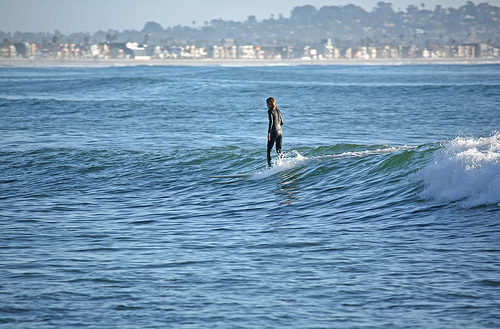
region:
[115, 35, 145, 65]
Small building in the corner of water.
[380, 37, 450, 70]
Small building in the corner of water.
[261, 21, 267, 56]
Small building in the corner of water.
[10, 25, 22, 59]
Small building in the corner of water.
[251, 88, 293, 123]
the head of a woman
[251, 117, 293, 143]
the hand of a person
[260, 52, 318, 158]
a person wearing a wet suit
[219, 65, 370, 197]
a person in the water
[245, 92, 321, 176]
a person on a surfboard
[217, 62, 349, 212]
a person surfing in the water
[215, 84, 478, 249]
a wave on the water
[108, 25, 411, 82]
building in the background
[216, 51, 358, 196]
a person riding a wave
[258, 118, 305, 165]
the legs of a person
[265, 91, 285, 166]
a person in a wetsuit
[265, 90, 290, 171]
a woman surfing on a small wave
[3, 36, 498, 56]
city buildings along the shore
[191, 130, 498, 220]
a small wave the woman is surfing on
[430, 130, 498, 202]
white water of a breaking wave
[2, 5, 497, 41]
trees behind the city on the shore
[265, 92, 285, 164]
a girl riding on a surfboard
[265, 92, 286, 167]
a surfer in the blue water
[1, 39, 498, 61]
buildings lined up on the shore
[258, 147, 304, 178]
white water made by the surfboard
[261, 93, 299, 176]
A woman stands on a surfboard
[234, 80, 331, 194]
A woman is surfing on the water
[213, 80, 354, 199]
A woman surfs on the ocean waves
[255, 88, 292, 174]
The woman is wearing a black swimsuit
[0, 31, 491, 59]
A city view is in the distance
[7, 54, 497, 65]
A beach is in the distance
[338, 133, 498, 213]
Ocean waves build in the water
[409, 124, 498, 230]
Foam is forming on top of the water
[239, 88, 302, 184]
The woman surfs on a surfboard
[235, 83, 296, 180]
The woman wears a black suit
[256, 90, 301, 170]
woman in a wet suit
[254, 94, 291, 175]
a person in a wet suit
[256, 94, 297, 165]
woman is on her surfboard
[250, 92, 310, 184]
woman is surfing through the small tides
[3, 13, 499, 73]
the bay of the city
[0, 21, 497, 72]
view of the city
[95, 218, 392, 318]
a body of bay water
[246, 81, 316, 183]
a woman is surfing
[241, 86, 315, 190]
a person is surfing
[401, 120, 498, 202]
tides of an ocean